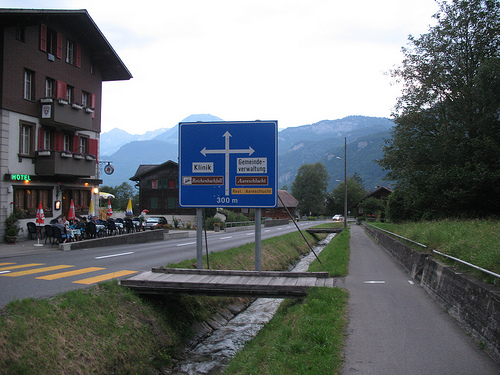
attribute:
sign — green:
[7, 167, 37, 190]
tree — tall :
[376, 2, 499, 222]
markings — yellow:
[28, 246, 135, 296]